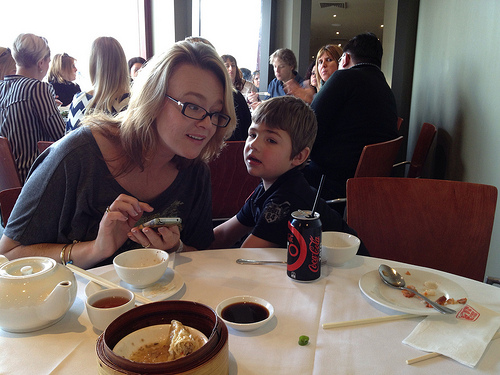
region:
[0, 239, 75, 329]
White tea kettle on table.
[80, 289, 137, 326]
White tea cup filled with tea.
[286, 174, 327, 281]
A cocacola zero can with a straw in it.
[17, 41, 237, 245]
A woman with glasses holding a telephone.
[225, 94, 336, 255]
A boy sitting at the table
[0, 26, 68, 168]
A woman with a black and white striped shirt.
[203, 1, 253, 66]
Sunlight coming in through the windows.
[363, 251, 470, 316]
A plate with a spoon on it.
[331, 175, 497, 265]
The brown backing of a chair.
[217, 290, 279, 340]
A white bowl with soy sauce in it.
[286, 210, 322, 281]
black Coca Cola can with red writing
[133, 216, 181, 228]
cell phone the woman is holding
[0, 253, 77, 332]
short white tea pot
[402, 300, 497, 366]
white napkin with red writing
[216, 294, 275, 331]
small white bowl with brown liquid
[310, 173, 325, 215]
black straw in the Coke can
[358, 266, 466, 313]
white plate with food particles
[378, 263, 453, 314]
silver spoon on the white plate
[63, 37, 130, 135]
blonde woman in blue and white shirt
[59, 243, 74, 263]
two gold bangle bracelets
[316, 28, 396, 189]
person eating at restaurant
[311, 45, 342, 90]
person eating at restaurant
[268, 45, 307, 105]
person eating at restaurant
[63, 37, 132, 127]
person eating at restaurant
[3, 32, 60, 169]
person eating at restaurant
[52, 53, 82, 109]
person eating at restaurant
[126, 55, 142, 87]
person eating at restaurant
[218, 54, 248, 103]
person eating at restaurant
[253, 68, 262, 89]
person eating at restaurant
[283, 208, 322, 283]
soda can on table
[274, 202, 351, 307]
The coke can is black and red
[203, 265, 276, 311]
The table cloth is white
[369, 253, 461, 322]
The plate has a spoon on it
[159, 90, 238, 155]
The woman has glasses on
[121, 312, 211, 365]
The food is in the dish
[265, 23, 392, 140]
People are in the back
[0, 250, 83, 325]
The tea pot is white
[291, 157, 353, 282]
The can has a straw in it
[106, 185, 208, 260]
The woman is holding a phone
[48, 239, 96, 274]
The woman has a bracelet on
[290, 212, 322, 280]
Black and red coke on table.